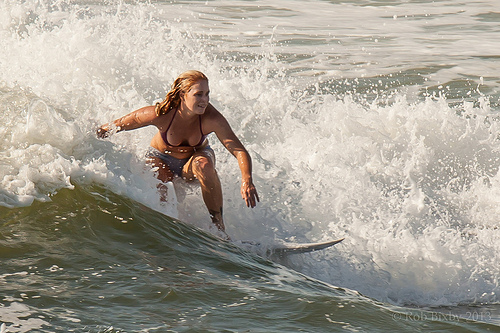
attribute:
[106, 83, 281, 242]
woman — pretty